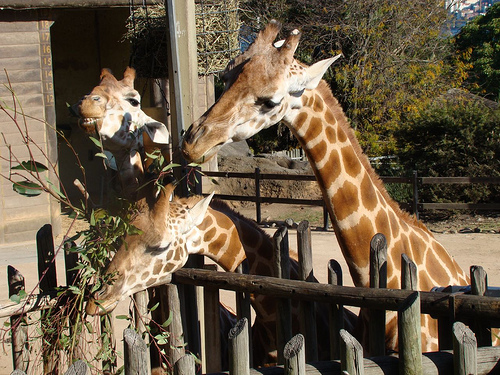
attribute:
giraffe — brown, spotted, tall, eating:
[173, 24, 332, 171]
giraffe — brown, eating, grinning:
[69, 65, 174, 182]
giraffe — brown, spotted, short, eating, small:
[77, 184, 254, 329]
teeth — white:
[77, 116, 103, 129]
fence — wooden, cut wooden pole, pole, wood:
[176, 250, 500, 343]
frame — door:
[159, 7, 197, 181]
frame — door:
[32, 12, 68, 209]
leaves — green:
[76, 213, 132, 280]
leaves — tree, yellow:
[333, 8, 484, 147]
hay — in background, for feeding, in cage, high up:
[125, 7, 249, 68]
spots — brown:
[300, 97, 384, 236]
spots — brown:
[194, 218, 243, 262]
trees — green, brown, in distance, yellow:
[313, 3, 500, 158]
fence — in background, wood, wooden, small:
[195, 170, 495, 226]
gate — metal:
[403, 168, 427, 247]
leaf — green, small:
[14, 180, 43, 203]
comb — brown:
[331, 96, 358, 150]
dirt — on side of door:
[216, 151, 306, 213]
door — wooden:
[50, 11, 191, 200]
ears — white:
[150, 187, 217, 223]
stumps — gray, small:
[433, 227, 498, 238]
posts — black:
[246, 167, 270, 230]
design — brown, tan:
[311, 140, 384, 248]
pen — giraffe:
[11, 181, 500, 318]